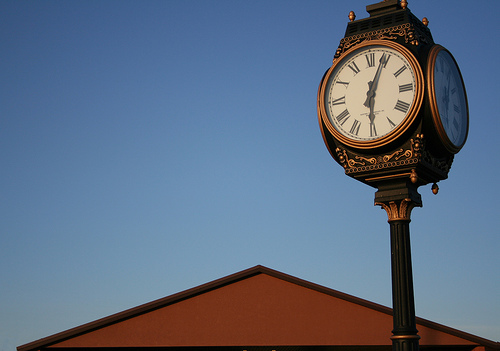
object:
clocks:
[427, 42, 472, 158]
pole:
[374, 179, 426, 344]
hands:
[366, 50, 385, 133]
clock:
[321, 43, 417, 143]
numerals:
[395, 82, 415, 94]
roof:
[19, 263, 495, 351]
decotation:
[374, 197, 422, 221]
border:
[319, 39, 427, 150]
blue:
[15, 9, 311, 151]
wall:
[181, 304, 340, 338]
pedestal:
[371, 178, 424, 208]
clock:
[316, 2, 471, 182]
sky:
[81, 7, 279, 76]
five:
[376, 52, 392, 70]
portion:
[112, 7, 302, 104]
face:
[427, 44, 471, 150]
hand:
[362, 53, 386, 108]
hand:
[366, 81, 378, 130]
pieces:
[427, 181, 441, 196]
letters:
[359, 108, 385, 116]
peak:
[248, 262, 271, 272]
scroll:
[355, 154, 378, 165]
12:
[364, 52, 374, 70]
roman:
[367, 122, 378, 137]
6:
[367, 122, 379, 138]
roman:
[330, 94, 348, 107]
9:
[330, 96, 347, 107]